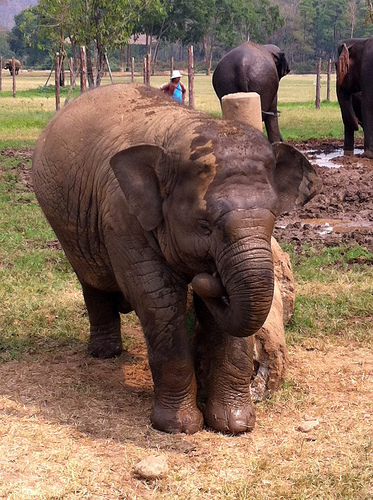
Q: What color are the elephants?
A: Brown.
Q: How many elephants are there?
A: Three.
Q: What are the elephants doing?
A: Standing.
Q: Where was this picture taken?
A: In a field.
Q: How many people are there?
A: One.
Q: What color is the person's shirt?
A: Blue.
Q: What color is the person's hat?
A: White.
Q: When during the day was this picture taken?
A: Daytime.